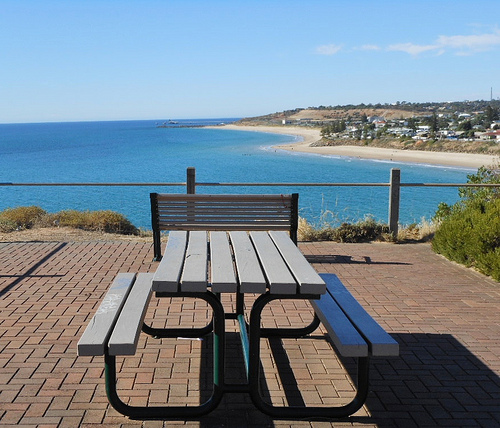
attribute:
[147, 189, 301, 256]
bench — wooden, metal, gray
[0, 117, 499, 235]
water — blue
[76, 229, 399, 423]
table — wooden, metal, gray, for picnics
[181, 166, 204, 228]
post — wooden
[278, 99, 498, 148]
houses — far, white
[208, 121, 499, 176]
beach — sandy, beautiful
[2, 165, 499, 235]
fence — brown, wooden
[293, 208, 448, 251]
bushes — gray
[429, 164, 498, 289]
bushes — green, growing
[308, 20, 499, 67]
clouds — white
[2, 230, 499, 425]
balcony — brick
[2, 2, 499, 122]
sky — clear